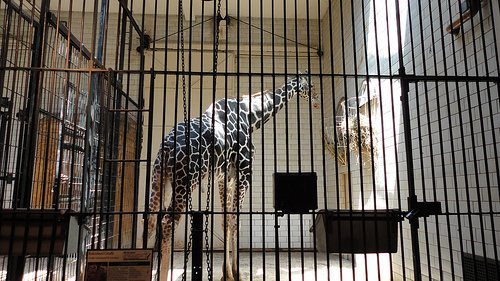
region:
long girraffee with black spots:
[152, 72, 311, 279]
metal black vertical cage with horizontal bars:
[3, 2, 496, 278]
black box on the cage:
[311, 211, 403, 253]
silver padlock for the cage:
[407, 208, 423, 220]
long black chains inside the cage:
[173, 1, 223, 280]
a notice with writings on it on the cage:
[82, 244, 155, 279]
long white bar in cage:
[144, 45, 324, 57]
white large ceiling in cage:
[4, 1, 327, 18]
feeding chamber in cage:
[319, 86, 383, 167]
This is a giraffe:
[118, 56, 335, 278]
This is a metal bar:
[260, 1, 268, 279]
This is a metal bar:
[267, 1, 287, 278]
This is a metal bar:
[278, 0, 294, 280]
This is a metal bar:
[292, 1, 309, 279]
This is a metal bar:
[305, 0, 320, 279]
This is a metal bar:
[316, 0, 335, 280]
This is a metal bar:
[160, 0, 171, 272]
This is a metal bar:
[338, 3, 347, 268]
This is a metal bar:
[392, 11, 417, 276]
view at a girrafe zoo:
[141, 37, 423, 279]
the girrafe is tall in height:
[163, 31, 341, 199]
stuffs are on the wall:
[307, 50, 402, 171]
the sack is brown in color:
[313, 89, 385, 164]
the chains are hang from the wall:
[178, 72, 239, 239]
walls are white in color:
[417, 102, 497, 165]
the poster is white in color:
[88, 242, 148, 280]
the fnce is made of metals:
[413, 81, 480, 224]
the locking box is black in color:
[268, 163, 325, 215]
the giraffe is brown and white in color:
[185, 113, 265, 206]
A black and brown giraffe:
[164, 91, 298, 274]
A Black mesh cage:
[414, 87, 496, 186]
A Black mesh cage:
[12, 178, 106, 268]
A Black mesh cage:
[3, 72, 120, 174]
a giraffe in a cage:
[62, 20, 407, 264]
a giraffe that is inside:
[89, 18, 344, 265]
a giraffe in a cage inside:
[41, 33, 493, 261]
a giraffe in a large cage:
[118, 36, 443, 257]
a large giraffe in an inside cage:
[64, 38, 449, 271]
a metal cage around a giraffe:
[92, 11, 377, 269]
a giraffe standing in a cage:
[119, 61, 431, 279]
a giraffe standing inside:
[133, 8, 440, 275]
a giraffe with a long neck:
[116, 46, 360, 275]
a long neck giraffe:
[152, 48, 344, 272]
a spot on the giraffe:
[210, 128, 231, 157]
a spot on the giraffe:
[140, 157, 175, 174]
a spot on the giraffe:
[162, 142, 179, 163]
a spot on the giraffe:
[181, 137, 190, 154]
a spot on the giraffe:
[256, 109, 263, 112]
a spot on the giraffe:
[235, 157, 258, 189]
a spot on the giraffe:
[237, 139, 247, 167]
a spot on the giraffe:
[233, 128, 253, 160]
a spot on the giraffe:
[210, 119, 222, 134]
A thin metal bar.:
[235, 70, 241, 218]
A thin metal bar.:
[244, 71, 255, 215]